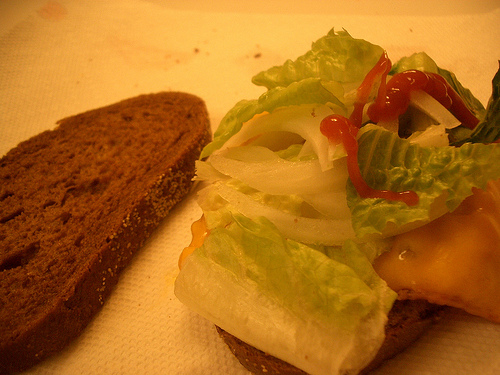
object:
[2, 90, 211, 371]
bread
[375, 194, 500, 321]
cheese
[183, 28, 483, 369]
lettuce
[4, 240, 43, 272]
hole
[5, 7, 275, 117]
cloth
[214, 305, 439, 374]
bread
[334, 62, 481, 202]
ketchup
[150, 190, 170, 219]
seeds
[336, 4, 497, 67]
napkin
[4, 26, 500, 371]
sandwich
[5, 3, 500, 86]
towel